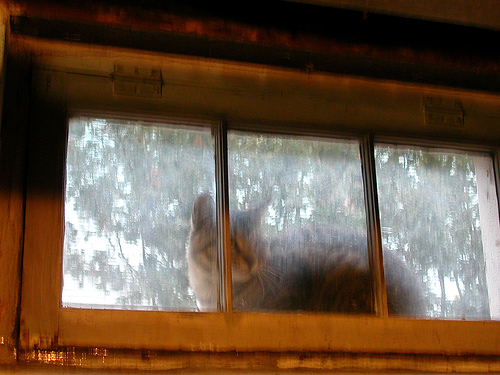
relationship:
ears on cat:
[183, 187, 224, 228] [166, 186, 311, 285]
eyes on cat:
[172, 219, 281, 250] [166, 186, 311, 285]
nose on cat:
[235, 243, 264, 265] [166, 186, 311, 285]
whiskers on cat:
[208, 254, 271, 294] [166, 186, 311, 285]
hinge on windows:
[344, 92, 475, 124] [66, 104, 475, 319]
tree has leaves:
[248, 143, 363, 220] [104, 153, 177, 192]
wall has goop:
[9, 216, 91, 358] [12, 328, 134, 365]